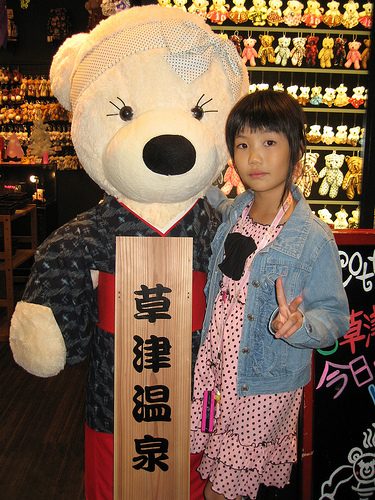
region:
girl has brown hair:
[233, 93, 292, 165]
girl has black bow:
[215, 228, 265, 284]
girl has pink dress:
[182, 203, 294, 483]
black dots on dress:
[193, 205, 329, 494]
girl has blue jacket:
[232, 197, 351, 395]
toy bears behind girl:
[138, 2, 366, 226]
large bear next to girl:
[52, 15, 256, 496]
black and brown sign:
[113, 224, 213, 497]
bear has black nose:
[151, 144, 206, 172]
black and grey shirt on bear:
[23, 201, 235, 464]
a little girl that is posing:
[203, 100, 348, 482]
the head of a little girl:
[229, 81, 306, 203]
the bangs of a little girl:
[235, 97, 288, 138]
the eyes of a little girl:
[229, 132, 280, 150]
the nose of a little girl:
[241, 148, 264, 163]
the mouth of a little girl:
[243, 163, 270, 181]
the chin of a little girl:
[246, 174, 270, 192]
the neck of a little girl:
[247, 183, 283, 228]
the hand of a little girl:
[270, 273, 308, 341]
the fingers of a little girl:
[265, 268, 302, 313]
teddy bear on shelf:
[339, 2, 358, 29]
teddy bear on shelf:
[324, 4, 341, 25]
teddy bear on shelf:
[304, 0, 322, 28]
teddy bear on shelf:
[266, 0, 284, 26]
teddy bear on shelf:
[210, 1, 228, 24]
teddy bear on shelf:
[348, 86, 363, 107]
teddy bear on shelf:
[318, 38, 334, 68]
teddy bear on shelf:
[291, 35, 303, 66]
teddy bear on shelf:
[316, 152, 343, 200]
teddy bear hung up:
[244, 34, 258, 60]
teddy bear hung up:
[259, 34, 271, 61]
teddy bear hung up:
[343, 3, 354, 30]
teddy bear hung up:
[322, 34, 332, 72]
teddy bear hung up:
[320, 122, 331, 142]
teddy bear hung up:
[349, 125, 360, 145]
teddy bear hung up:
[345, 153, 363, 200]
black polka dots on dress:
[227, 408, 275, 468]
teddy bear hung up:
[17, 73, 29, 93]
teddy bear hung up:
[207, 4, 226, 21]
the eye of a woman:
[233, 138, 249, 155]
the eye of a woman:
[260, 135, 281, 151]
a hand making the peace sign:
[266, 276, 309, 345]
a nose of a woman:
[246, 146, 263, 170]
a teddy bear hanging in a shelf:
[314, 150, 345, 199]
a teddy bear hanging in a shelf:
[316, 36, 335, 66]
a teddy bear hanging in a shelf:
[345, 35, 361, 71]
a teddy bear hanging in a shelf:
[302, 33, 320, 68]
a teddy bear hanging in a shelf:
[344, 150, 364, 205]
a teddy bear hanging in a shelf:
[255, 32, 275, 65]